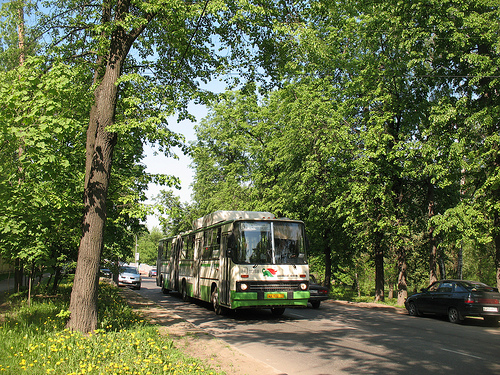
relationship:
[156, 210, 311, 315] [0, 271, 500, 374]
bus on ground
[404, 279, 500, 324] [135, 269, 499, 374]
car on street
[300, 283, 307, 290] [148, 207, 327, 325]
headlight on bus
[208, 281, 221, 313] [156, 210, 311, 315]
tire on bus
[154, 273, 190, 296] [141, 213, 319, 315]
tire on bus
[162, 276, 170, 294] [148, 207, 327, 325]
tire on bus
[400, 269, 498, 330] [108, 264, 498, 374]
car parked on street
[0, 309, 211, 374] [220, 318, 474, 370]
yellow flowers next to street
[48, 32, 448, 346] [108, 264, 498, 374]
trees on sides of street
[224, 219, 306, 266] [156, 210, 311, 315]
windshield on bus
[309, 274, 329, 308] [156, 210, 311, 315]
black car next to bus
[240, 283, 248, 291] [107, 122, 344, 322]
headlight on bus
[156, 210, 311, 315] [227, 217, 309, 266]
bus on front window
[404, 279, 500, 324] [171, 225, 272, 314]
car near bus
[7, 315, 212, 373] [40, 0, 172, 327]
yellow flowers by tree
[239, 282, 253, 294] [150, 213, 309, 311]
headlight on bus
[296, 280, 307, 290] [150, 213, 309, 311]
headlight on bus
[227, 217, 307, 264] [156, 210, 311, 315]
front window at front of bus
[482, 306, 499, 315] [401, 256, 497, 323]
license plate behind car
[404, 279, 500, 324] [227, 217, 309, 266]
car on side of front window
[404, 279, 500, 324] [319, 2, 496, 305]
car parked under trees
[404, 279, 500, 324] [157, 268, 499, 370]
car on road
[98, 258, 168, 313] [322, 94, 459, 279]
car next to trees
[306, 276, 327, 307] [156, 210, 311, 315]
black car passing bus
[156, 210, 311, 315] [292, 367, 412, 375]
bus on road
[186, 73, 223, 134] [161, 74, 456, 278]
sky behind trees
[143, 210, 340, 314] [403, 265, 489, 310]
bus passing car